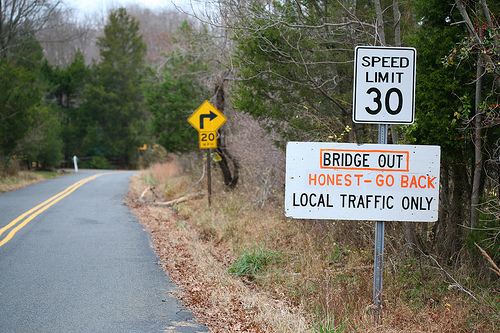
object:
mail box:
[73, 155, 78, 172]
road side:
[0, 169, 211, 330]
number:
[201, 133, 207, 141]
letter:
[396, 154, 404, 168]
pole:
[372, 124, 387, 311]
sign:
[137, 143, 147, 150]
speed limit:
[360, 54, 408, 116]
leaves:
[238, 54, 299, 108]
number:
[365, 87, 403, 115]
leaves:
[439, 26, 499, 123]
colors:
[470, 30, 490, 44]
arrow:
[200, 111, 217, 129]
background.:
[0, 0, 500, 333]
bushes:
[0, 0, 500, 333]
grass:
[128, 157, 496, 332]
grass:
[0, 169, 77, 192]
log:
[139, 183, 206, 206]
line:
[0, 173, 103, 250]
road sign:
[351, 46, 416, 125]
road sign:
[284, 142, 441, 222]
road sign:
[187, 99, 227, 149]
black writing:
[362, 56, 409, 69]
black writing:
[366, 72, 403, 84]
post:
[187, 100, 226, 207]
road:
[0, 169, 210, 333]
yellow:
[209, 122, 219, 128]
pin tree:
[0, 7, 202, 170]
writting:
[364, 86, 403, 115]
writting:
[292, 192, 436, 210]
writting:
[201, 133, 215, 141]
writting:
[308, 153, 436, 189]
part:
[365, 87, 383, 116]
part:
[373, 221, 384, 305]